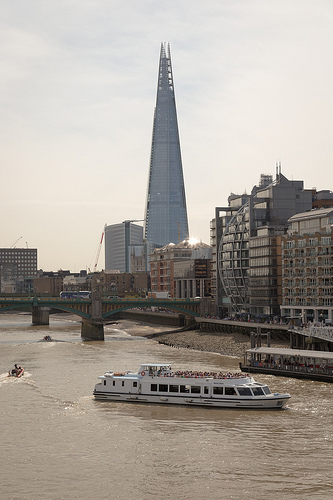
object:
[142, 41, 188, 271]
building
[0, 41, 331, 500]
city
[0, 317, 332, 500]
river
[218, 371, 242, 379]
people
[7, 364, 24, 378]
boat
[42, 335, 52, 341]
boat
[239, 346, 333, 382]
boat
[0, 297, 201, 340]
bridge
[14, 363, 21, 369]
people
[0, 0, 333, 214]
sky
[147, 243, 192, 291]
building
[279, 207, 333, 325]
building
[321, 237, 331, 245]
windows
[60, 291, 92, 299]
bus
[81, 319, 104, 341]
concrete support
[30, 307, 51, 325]
concrete support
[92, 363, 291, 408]
boats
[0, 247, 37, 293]
buildings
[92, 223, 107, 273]
crane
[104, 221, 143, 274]
building